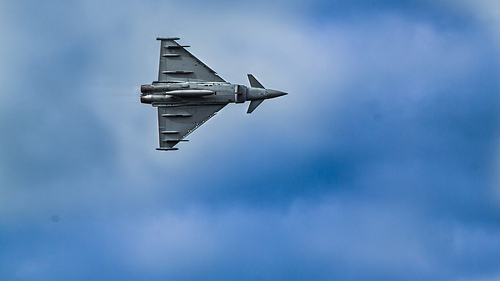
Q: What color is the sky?
A: Blue.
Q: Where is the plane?
A: In the air.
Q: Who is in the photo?
A: Nobody.